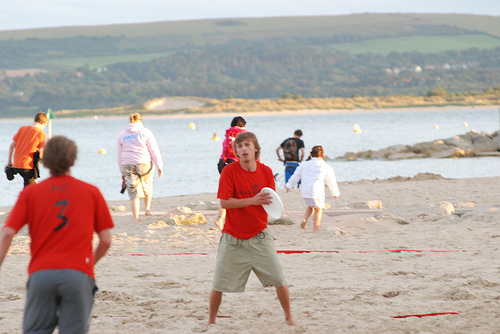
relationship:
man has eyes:
[193, 132, 298, 312] [234, 140, 251, 150]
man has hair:
[207, 132, 299, 328] [229, 130, 261, 159]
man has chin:
[207, 132, 299, 328] [242, 155, 254, 161]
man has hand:
[207, 132, 299, 328] [252, 190, 271, 210]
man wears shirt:
[207, 132, 299, 328] [213, 156, 278, 237]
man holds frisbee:
[207, 132, 299, 328] [258, 185, 285, 220]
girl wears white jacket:
[284, 145, 341, 234] [285, 155, 339, 200]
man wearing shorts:
[0, 135, 115, 334] [20, 269, 95, 329]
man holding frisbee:
[207, 132, 299, 328] [259, 186, 284, 221]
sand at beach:
[0, 177, 497, 332] [1, 104, 499, 332]